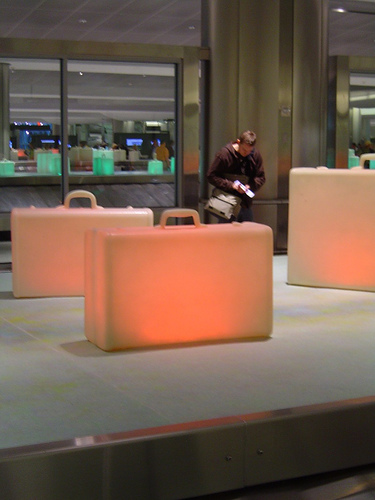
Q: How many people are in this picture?
A: 1.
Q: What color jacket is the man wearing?
A: Brown.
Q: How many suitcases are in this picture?
A: 3.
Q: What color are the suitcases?
A: White.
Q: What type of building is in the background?
A: Store.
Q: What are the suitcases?
A: Lights.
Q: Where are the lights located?
A: Inside suitcases.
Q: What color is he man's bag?
A: Tan.